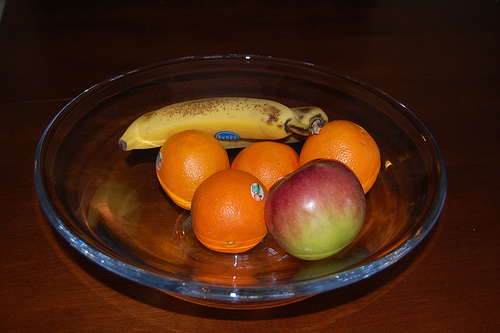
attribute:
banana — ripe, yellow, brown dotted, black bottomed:
[96, 91, 340, 149]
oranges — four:
[142, 120, 371, 246]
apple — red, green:
[244, 153, 381, 265]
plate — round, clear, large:
[31, 38, 477, 308]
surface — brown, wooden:
[5, 2, 493, 327]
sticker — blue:
[213, 123, 246, 147]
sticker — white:
[244, 178, 265, 202]